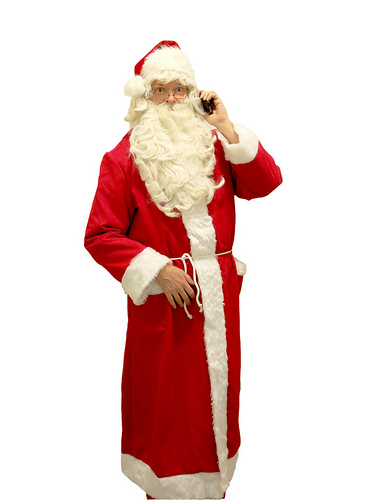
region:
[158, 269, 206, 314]
hand of santa claus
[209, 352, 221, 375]
fur on santa claus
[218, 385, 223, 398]
fur on santa claus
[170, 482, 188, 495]
fur on santa claus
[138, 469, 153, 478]
fur on santa claus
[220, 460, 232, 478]
fur on santa claus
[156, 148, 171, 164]
fur on santa claus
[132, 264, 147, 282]
fur on santa claus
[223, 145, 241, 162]
fur on santa claus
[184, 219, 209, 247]
fur on santa claus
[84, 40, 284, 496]
Santa Claus has a cell phone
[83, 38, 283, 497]
tall man in Santa Claus costume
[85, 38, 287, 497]
Santa's got a cellphone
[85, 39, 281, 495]
Santa Claus in ankle length coat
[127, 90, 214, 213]
fake white Santa Claus beard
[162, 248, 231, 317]
think white rope belt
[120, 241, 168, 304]
fake white fur trim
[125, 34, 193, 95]
Santa Claus cap with white pom pom and trim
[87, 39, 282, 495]
Santa Claus on his cell phone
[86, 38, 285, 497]
man dressed in Santa Claus costume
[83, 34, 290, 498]
man wearing a santa robe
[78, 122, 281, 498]
red and white robe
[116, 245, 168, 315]
white fur around the cuff of the sleeve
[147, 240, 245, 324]
white string tied around the robe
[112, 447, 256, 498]
white trim on the bottom of the robe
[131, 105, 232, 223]
long, thick, white beard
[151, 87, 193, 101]
glasses on the face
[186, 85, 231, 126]
hand holding a phone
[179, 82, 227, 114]
phone lifted up to the ear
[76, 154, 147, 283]
wrinkles on the sleeve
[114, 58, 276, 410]
this is a man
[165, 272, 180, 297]
the man is light skinned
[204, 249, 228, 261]
this is a rope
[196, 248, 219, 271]
the rope is white in color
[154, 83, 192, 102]
this is a spectacle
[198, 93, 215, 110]
this is a phone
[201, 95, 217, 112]
the phone is black in color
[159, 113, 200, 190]
this is the beard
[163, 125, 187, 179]
the beards is white in color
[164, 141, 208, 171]
the beard is long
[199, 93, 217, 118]
a dark cell phone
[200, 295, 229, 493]
some white faux fur trim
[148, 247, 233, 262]
a thin white cord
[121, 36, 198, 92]
a red and white hat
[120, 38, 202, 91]
a fur lined christmas hat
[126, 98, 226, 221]
a long white beard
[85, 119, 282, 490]
a long red coat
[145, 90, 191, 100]
some wire rimmed glasses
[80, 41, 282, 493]
santa claus talking on the phone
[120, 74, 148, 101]
a furry white ball